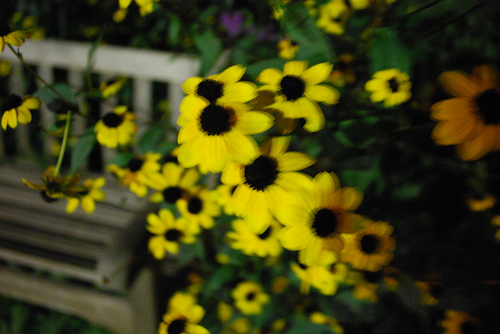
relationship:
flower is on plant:
[143, 163, 201, 201] [9, 7, 496, 332]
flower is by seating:
[176, 94, 275, 175] [3, 43, 203, 333]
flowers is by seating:
[223, 137, 310, 233] [3, 43, 203, 333]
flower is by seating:
[255, 59, 341, 133] [3, 43, 203, 333]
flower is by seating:
[118, 149, 161, 187] [3, 43, 203, 333]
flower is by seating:
[93, 105, 138, 150] [3, 43, 203, 333]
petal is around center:
[202, 140, 222, 173] [195, 105, 230, 135]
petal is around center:
[226, 132, 252, 157] [195, 105, 230, 135]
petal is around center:
[236, 110, 271, 130] [195, 105, 230, 135]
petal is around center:
[173, 122, 198, 142] [195, 105, 230, 135]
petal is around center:
[178, 134, 198, 163] [195, 105, 230, 135]